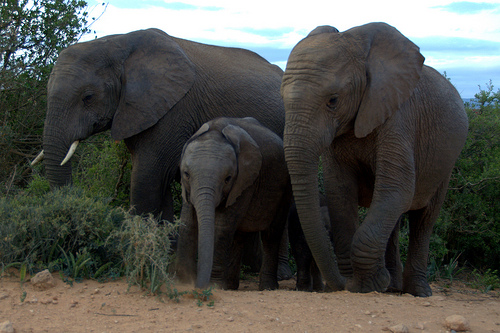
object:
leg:
[347, 155, 414, 293]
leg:
[257, 226, 279, 291]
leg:
[404, 210, 433, 298]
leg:
[288, 215, 314, 291]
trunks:
[283, 124, 349, 289]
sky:
[1, 0, 498, 97]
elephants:
[31, 28, 293, 282]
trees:
[0, 0, 106, 70]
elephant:
[281, 20, 469, 298]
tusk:
[29, 150, 43, 166]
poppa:
[29, 27, 294, 281]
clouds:
[422, 51, 500, 69]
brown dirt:
[0, 268, 498, 331]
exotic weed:
[0, 181, 176, 298]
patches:
[421, 38, 498, 55]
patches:
[442, 0, 494, 13]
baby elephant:
[171, 116, 310, 290]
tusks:
[60, 140, 80, 166]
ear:
[353, 23, 425, 139]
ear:
[222, 124, 263, 208]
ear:
[108, 29, 198, 142]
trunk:
[190, 182, 222, 289]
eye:
[184, 170, 190, 178]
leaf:
[82, 11, 88, 16]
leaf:
[94, 35, 97, 39]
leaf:
[17, 57, 21, 62]